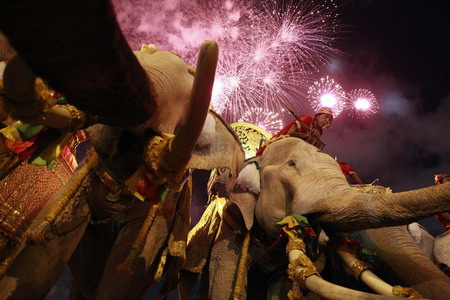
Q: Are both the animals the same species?
A: Yes, all the animals are elephants.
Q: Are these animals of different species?
A: No, all the animals are elephants.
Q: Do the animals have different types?
A: No, all the animals are elephants.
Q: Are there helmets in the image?
A: No, there are no helmets.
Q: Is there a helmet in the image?
A: No, there are no helmets.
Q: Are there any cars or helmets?
A: No, there are no helmets or cars.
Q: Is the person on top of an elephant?
A: Yes, the person is on top of an elephant.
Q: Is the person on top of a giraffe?
A: No, the person is on top of an elephant.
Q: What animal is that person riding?
A: The person is riding an elephant.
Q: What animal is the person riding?
A: The person is riding an elephant.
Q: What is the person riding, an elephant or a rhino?
A: The person is riding an elephant.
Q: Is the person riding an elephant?
A: Yes, the person is riding an elephant.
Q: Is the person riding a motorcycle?
A: No, the person is riding an elephant.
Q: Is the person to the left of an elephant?
A: No, the person is to the right of an elephant.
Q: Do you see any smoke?
A: Yes, there is smoke.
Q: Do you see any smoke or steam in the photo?
A: Yes, there is smoke.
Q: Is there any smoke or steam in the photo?
A: Yes, there is smoke.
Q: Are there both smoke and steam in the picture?
A: No, there is smoke but no steam.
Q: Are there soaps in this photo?
A: No, there are no soaps.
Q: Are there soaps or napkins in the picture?
A: No, there are no soaps or napkins.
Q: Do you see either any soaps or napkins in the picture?
A: No, there are no soaps or napkins.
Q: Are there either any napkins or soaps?
A: No, there are no soaps or napkins.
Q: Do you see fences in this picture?
A: No, there are no fences.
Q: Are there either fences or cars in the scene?
A: No, there are no fences or cars.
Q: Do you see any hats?
A: Yes, there is a hat.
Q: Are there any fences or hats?
A: Yes, there is a hat.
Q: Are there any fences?
A: No, there are no fences.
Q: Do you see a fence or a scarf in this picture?
A: No, there are no fences or scarves.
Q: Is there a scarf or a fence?
A: No, there are no fences or scarves.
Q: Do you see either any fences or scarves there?
A: No, there are no fences or scarves.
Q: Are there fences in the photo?
A: No, there are no fences.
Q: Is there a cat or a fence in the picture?
A: No, there are no fences or cats.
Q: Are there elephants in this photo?
A: Yes, there is an elephant.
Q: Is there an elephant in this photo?
A: Yes, there is an elephant.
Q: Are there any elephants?
A: Yes, there is an elephant.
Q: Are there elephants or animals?
A: Yes, there is an elephant.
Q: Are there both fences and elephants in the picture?
A: No, there is an elephant but no fences.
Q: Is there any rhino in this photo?
A: No, there are no rhinos.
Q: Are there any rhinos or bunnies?
A: No, there are no rhinos or bunnies.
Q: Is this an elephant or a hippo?
A: This is an elephant.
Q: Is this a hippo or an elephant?
A: This is an elephant.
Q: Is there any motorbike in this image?
A: No, there are no motorcycles.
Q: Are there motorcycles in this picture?
A: No, there are no motorcycles.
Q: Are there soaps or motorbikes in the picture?
A: No, there are no motorbikes or soaps.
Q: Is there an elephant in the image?
A: Yes, there is an elephant.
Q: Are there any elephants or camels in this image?
A: Yes, there is an elephant.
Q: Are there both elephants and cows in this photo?
A: No, there is an elephant but no cows.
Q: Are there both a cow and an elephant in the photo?
A: No, there is an elephant but no cows.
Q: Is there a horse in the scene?
A: No, there are no horses.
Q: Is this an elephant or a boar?
A: This is an elephant.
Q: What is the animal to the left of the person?
A: The animal is an elephant.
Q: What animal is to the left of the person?
A: The animal is an elephant.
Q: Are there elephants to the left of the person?
A: Yes, there is an elephant to the left of the person.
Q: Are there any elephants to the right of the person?
A: No, the elephant is to the left of the person.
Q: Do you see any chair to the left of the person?
A: No, there is an elephant to the left of the person.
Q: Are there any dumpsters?
A: No, there are no dumpsters.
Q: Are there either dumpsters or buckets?
A: No, there are no dumpsters or buckets.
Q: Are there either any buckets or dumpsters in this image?
A: No, there are no dumpsters or buckets.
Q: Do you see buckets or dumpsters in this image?
A: No, there are no dumpsters or buckets.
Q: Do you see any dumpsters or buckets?
A: No, there are no dumpsters or buckets.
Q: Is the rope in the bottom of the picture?
A: Yes, the rope is in the bottom of the image.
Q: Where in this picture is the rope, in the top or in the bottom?
A: The rope is in the bottom of the image.